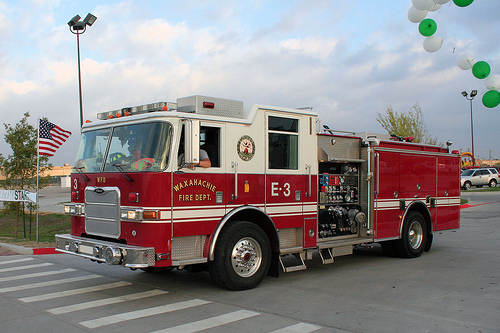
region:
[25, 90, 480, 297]
The firetruck is on the street.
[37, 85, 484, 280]
The firetruck is at a crosswalk.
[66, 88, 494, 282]
The firetruck is red and white.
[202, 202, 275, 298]
The firetruck has a big tire.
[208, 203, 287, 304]
The firetruck tire is black.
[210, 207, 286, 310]
The firetruck tire is black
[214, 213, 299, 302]
The firetruck tire is round.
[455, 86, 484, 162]
The streetlight is off.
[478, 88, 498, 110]
The balloon is green.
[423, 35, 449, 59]
The balloon is white.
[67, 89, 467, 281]
a red and white fire truck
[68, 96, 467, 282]
a red and white fire engine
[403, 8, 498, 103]
green and white balloons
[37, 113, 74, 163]
an American flag on a pole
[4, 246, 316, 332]
a crosswalk in a street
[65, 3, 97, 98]
lights on a pole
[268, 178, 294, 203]
the letter E and number three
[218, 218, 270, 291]
tire on a fire truck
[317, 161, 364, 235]
controls on a fire truck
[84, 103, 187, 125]
lights on a fire truck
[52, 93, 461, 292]
Fire truck on the road.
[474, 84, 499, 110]
Green balloon in the air.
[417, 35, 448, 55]
White balloon in the air.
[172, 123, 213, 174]
Person driving the fire truck.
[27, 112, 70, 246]
Flag on the pole.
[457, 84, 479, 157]
Street lights in the background.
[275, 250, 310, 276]
Step on fire truck.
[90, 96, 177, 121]
Lights on the fire truck.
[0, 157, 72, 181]
Building in the background.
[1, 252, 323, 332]
White lines on the pavement.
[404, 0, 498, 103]
green and white balloons in the aire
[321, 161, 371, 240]
you can see the fire truck tool panel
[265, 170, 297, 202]
the fire truck has E-3 on it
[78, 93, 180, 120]
the fire truck has lights on the top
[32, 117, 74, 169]
A United States flag flying.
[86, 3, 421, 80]
the sky is cloudy with some clearing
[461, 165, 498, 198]
a silver SUV parked behind the fire truck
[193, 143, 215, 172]
you can see the arm of the fire truck diver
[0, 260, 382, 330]
the road has white lines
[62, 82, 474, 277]
red and white fire enginer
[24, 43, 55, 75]
white clouds in blue sky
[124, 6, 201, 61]
white clouds in blue sky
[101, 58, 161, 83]
white clouds in blue sky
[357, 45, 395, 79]
white clouds in blue sky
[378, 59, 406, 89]
white clouds in blue sky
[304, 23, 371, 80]
white clouds in blue sky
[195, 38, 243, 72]
white clouds in blue sky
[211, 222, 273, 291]
Tire of a fire truck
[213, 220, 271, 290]
Large tire of a fire truck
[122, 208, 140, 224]
Headlight of a vehicle